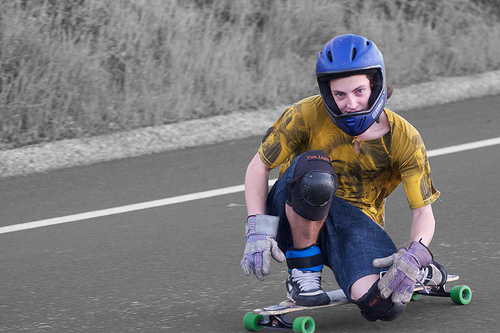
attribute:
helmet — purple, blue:
[316, 34, 390, 137]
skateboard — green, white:
[242, 273, 473, 332]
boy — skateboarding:
[242, 33, 446, 321]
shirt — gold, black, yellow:
[258, 93, 439, 229]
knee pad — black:
[288, 152, 337, 221]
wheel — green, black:
[411, 291, 423, 300]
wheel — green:
[292, 316, 315, 332]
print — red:
[306, 154, 332, 161]